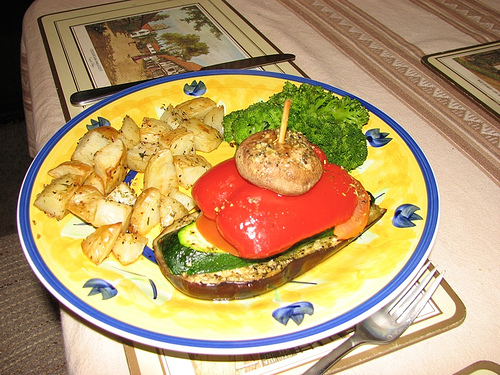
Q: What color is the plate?
A: Yellow.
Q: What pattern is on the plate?
A: Flowers.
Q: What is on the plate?
A: Sandwich.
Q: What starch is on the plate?
A: Potatoes.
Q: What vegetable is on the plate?
A: Broccoli.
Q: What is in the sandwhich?
A: Toothpick.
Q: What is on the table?
A: Table cloth.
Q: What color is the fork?
A: Silver.